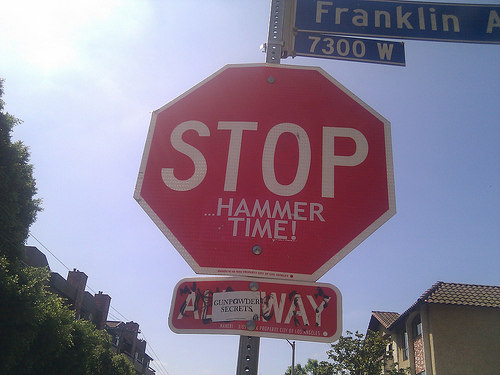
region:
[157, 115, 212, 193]
white letter S on sign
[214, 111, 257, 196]
white letter T on sign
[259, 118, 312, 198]
white letter O on sign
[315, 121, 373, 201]
white letter P on sign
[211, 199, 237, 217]
white letter H on sign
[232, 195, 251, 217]
white letter A on sign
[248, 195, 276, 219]
white letter M on sign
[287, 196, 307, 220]
white letter E on sign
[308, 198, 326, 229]
white letter R on sign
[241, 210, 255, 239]
white letter I on sign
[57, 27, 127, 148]
A blue color sky with clouds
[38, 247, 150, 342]
Buildings near the tree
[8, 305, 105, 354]
Tree near the sign board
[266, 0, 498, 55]
Street name with stop sign board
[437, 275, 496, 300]
Roof of the building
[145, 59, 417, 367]
Metal post with stop sign board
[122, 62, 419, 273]
Octogonal shape of the sign board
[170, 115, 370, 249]
Text written in white color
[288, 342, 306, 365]
Street light with metal post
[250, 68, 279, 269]
Bolts in the stop sign board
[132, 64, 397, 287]
A red and white octagon stop sign.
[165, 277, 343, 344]
A red and white ALL WAY sign with marks and a sticker on it.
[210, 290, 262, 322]
A white sticker that says GUNPOWDER SECRETS.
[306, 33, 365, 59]
The number 7300.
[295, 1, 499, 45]
A blue street sign that says Franklin A.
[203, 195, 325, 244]
White letters that say ...HAMMER TIME!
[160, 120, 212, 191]
Large white S in STOP.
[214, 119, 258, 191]
Large white T in STOP.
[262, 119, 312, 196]
Large white O in STOP.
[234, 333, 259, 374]
Silver pole with holes in it holding up signs.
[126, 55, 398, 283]
Stop sign on a pole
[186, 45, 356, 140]
Stop sign on a pole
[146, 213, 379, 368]
Stop sign on a pole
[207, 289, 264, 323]
Sticker on a traffic sign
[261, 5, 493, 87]
Street sign on a pole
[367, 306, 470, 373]
House behind the tree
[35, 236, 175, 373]
Electric lines in the sky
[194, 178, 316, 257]
Hammer Time on a stop sign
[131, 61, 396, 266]
Stop sign on the corner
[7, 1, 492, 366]
homes in back of traffic and address signs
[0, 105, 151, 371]
trees in front of buildings with chimneys and windows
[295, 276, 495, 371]
trees in front of brown homes with tiled and slanted roofs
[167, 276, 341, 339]
sticker and black marks on rectangular sign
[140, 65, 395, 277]
red and white traffic sign with additional words added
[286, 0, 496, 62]
name of street over sign with numbers and direction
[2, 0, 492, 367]
sun shining through white cloud in blue sky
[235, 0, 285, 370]
signs attached to flat metal support with holes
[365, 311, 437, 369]
stone and green panels on front of home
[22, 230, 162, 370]
wires stretched across tops of buildings